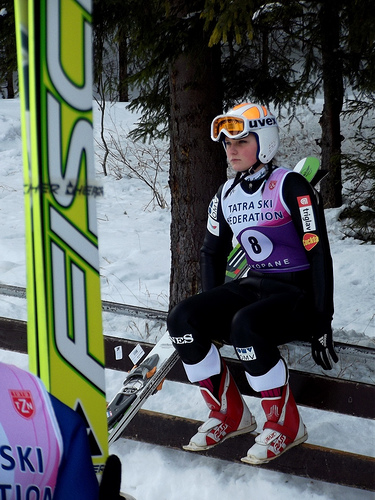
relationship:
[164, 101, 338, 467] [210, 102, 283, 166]
woman wearing helmet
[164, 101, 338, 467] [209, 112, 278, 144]
woman wearing goggles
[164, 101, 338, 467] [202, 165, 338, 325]
woman wears top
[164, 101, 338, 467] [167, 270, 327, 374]
woman wears pants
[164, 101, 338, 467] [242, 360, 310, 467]
woman wears shoes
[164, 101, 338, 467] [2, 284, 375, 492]
woman sits on ledge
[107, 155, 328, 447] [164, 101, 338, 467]
skis belong to woman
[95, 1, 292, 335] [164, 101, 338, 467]
tree behind woman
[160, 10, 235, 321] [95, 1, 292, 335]
trunk apart of tree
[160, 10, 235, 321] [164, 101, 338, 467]
trunk behind woman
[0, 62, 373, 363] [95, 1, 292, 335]
snow next to tree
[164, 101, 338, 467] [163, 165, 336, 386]
woman wearing snow suit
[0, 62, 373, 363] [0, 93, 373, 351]
snow on ground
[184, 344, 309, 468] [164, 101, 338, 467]
feet belong to woman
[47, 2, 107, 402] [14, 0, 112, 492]
words are on gear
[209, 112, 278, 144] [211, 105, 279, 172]
goggles are on head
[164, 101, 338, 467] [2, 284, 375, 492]
woman sitting on ledge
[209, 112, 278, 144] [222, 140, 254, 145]
goggles are to protect eyes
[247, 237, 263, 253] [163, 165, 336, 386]
number on snow suit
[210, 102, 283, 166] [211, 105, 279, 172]
helmet on head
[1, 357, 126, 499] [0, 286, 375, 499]
skier in foreground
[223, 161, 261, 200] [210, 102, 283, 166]
strap apart of helmet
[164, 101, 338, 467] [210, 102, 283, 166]
woman has helmet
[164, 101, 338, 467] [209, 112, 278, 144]
woman has goggles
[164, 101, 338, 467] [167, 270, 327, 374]
woman has pants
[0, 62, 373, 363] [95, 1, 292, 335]
snow beside tree